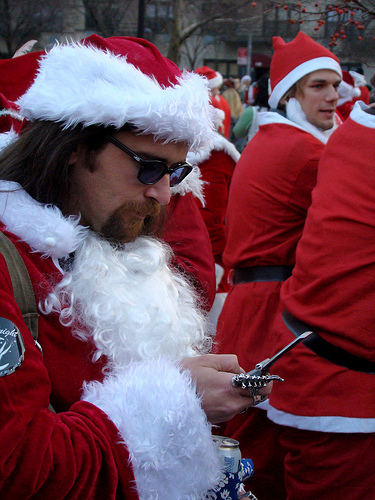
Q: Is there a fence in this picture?
A: No, there are no fences.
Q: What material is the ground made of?
A: The ground is made of brick.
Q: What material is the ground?
A: The ground is made of brick.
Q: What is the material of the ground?
A: The ground is made of brick.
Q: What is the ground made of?
A: The ground is made of brick.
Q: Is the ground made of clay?
A: No, the ground is made of brick.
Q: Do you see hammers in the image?
A: No, there are no hammers.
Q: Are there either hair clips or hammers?
A: No, there are no hammers or hair clips.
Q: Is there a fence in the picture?
A: No, there are no fences.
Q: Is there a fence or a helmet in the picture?
A: No, there are no fences or helmets.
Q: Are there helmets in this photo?
A: No, there are no helmets.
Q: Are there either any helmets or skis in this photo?
A: No, there are no helmets or skis.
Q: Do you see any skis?
A: No, there are no skis.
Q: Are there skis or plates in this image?
A: No, there are no skis or plates.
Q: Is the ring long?
A: Yes, the ring is long.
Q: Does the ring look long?
A: Yes, the ring is long.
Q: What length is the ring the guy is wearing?
A: The ring is long.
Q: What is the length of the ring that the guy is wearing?
A: The ring is long.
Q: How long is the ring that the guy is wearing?
A: The ring is long.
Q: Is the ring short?
A: No, the ring is long.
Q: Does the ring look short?
A: No, the ring is long.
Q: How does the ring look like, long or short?
A: The ring is long.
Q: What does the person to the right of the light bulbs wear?
A: The person wears a belt.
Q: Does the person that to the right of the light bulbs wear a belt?
A: Yes, the person wears a belt.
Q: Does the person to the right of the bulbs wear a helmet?
A: No, the person wears a belt.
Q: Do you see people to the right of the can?
A: Yes, there is a person to the right of the can.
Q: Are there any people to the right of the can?
A: Yes, there is a person to the right of the can.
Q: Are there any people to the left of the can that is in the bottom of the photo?
A: No, the person is to the right of the can.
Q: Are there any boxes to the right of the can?
A: No, there is a person to the right of the can.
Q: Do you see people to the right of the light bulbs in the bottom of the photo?
A: Yes, there is a person to the right of the bulbs.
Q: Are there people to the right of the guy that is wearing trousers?
A: Yes, there is a person to the right of the guy.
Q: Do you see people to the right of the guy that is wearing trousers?
A: Yes, there is a person to the right of the guy.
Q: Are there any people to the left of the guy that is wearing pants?
A: No, the person is to the right of the guy.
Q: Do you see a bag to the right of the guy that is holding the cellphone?
A: No, there is a person to the right of the guy.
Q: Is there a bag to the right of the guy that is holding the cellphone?
A: No, there is a person to the right of the guy.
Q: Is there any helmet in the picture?
A: No, there are no helmets.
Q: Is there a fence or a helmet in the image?
A: No, there are no helmets or fences.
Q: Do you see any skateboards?
A: No, there are no skateboards.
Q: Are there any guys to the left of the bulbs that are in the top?
A: Yes, there is a guy to the left of the light bulbs.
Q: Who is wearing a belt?
A: The guy is wearing a belt.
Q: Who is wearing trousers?
A: The guy is wearing trousers.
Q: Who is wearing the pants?
A: The guy is wearing trousers.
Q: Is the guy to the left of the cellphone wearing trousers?
A: Yes, the guy is wearing trousers.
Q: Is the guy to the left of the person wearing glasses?
A: No, the guy is wearing trousers.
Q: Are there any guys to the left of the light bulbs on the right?
A: Yes, there is a guy to the left of the light bulbs.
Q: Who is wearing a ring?
A: The guy is wearing a ring.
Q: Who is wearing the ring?
A: The guy is wearing a ring.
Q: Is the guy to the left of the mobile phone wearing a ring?
A: Yes, the guy is wearing a ring.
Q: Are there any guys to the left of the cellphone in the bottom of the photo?
A: Yes, there is a guy to the left of the cell phone.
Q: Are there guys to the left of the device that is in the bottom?
A: Yes, there is a guy to the left of the cell phone.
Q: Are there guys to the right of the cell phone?
A: No, the guy is to the left of the cell phone.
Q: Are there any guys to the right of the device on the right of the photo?
A: No, the guy is to the left of the cell phone.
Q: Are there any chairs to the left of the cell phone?
A: No, there is a guy to the left of the cell phone.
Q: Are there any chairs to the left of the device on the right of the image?
A: No, there is a guy to the left of the cell phone.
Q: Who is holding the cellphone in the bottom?
A: The guy is holding the cellphone.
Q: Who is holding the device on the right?
A: The guy is holding the cellphone.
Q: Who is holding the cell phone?
A: The guy is holding the cellphone.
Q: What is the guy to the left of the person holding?
A: The guy is holding the cellphone.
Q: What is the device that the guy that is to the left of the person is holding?
A: The device is a cell phone.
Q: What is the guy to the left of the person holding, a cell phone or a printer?
A: The guy is holding a cell phone.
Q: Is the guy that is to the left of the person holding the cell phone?
A: Yes, the guy is holding the cell phone.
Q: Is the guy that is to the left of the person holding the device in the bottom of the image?
A: Yes, the guy is holding the cell phone.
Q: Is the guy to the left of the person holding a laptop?
A: No, the guy is holding the cell phone.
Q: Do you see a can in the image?
A: Yes, there is a can.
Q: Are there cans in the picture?
A: Yes, there is a can.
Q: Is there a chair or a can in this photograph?
A: Yes, there is a can.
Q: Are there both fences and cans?
A: No, there is a can but no fences.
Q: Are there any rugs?
A: No, there are no rugs.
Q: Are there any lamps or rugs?
A: No, there are no rugs or lamps.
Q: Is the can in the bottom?
A: Yes, the can is in the bottom of the image.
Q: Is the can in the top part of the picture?
A: No, the can is in the bottom of the image.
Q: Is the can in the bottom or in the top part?
A: The can is in the bottom of the image.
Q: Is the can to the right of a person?
A: No, the can is to the left of a person.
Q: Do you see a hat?
A: Yes, there is a hat.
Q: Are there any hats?
A: Yes, there is a hat.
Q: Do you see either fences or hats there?
A: Yes, there is a hat.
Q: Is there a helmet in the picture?
A: No, there are no helmets.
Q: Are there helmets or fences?
A: No, there are no helmets or fences.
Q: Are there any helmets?
A: No, there are no helmets.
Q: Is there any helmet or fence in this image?
A: No, there are no helmets or fences.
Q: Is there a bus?
A: No, there are no buses.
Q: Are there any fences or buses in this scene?
A: No, there are no buses or fences.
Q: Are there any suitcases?
A: No, there are no suitcases.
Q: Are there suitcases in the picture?
A: No, there are no suitcases.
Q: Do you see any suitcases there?
A: No, there are no suitcases.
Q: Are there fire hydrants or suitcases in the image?
A: No, there are no suitcases or fire hydrants.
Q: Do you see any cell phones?
A: Yes, there is a cell phone.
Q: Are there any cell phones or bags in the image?
A: Yes, there is a cell phone.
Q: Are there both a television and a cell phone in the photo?
A: No, there is a cell phone but no televisions.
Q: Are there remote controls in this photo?
A: No, there are no remote controls.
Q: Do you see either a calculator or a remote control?
A: No, there are no remote controls or calculators.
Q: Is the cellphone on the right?
A: Yes, the cellphone is on the right of the image.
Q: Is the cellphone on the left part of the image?
A: No, the cellphone is on the right of the image.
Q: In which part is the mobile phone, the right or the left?
A: The mobile phone is on the right of the image.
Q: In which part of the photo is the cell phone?
A: The cell phone is on the right of the image.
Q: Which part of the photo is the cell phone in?
A: The cell phone is on the right of the image.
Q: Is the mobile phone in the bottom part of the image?
A: Yes, the mobile phone is in the bottom of the image.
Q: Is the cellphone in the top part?
A: No, the cellphone is in the bottom of the image.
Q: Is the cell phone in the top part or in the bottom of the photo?
A: The cell phone is in the bottom of the image.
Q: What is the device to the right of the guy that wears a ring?
A: The device is a cell phone.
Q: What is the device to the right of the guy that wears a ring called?
A: The device is a cell phone.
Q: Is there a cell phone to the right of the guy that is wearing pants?
A: Yes, there is a cell phone to the right of the guy.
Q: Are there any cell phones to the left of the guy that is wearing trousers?
A: No, the cell phone is to the right of the guy.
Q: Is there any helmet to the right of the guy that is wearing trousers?
A: No, there is a cell phone to the right of the guy.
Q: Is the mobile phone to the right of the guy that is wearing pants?
A: Yes, the mobile phone is to the right of the guy.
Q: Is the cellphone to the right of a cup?
A: No, the cellphone is to the right of the guy.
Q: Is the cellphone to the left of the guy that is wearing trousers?
A: No, the cellphone is to the right of the guy.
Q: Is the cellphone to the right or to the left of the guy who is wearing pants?
A: The cellphone is to the right of the guy.